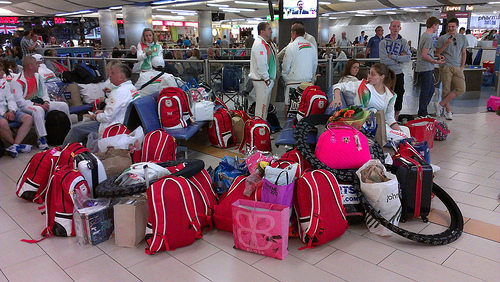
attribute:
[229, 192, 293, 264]
gift — pink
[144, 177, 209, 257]
backpack — red, carry on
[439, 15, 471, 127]
person — standing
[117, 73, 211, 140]
chair — blue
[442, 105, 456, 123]
shoe — white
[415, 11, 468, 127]
people — talking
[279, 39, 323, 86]
jacket — white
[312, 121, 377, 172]
bag — pink, carry on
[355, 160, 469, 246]
wheel — sitting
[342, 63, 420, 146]
woman — looking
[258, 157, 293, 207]
bag — purple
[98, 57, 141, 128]
man — old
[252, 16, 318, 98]
men — talking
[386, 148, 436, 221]
suitcase — black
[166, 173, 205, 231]
trim — white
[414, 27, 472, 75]
tee shirts — grey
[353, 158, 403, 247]
bag — white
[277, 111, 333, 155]
bench — blue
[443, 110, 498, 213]
floor — tile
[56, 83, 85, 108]
sack — brown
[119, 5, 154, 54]
pillar — white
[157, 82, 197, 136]
carry on — red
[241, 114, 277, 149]
carry on — red, carry on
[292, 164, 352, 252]
backpack — carry on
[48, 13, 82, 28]
sign — black